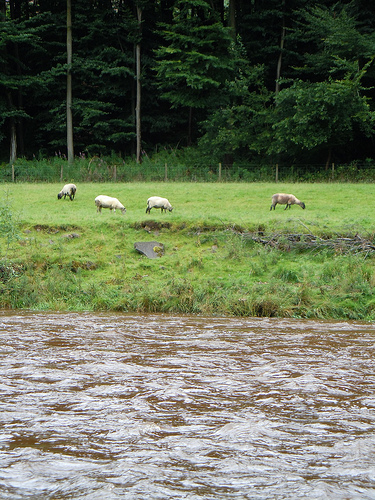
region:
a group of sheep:
[52, 172, 170, 225]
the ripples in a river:
[64, 435, 124, 482]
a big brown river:
[33, 313, 324, 486]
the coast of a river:
[153, 300, 191, 333]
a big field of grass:
[117, 267, 169, 304]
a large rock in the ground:
[126, 241, 174, 263]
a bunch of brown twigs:
[257, 221, 333, 255]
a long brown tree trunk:
[123, 87, 149, 154]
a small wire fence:
[123, 160, 261, 185]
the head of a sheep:
[117, 195, 129, 219]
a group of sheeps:
[37, 156, 365, 244]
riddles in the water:
[125, 433, 213, 485]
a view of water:
[1, 294, 372, 479]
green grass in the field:
[49, 229, 297, 305]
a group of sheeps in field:
[47, 173, 365, 248]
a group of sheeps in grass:
[54, 160, 345, 254]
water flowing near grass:
[34, 310, 349, 495]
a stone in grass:
[102, 224, 208, 279]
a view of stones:
[33, 210, 370, 271]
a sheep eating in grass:
[249, 173, 340, 238]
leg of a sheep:
[288, 201, 299, 211]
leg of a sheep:
[283, 200, 289, 215]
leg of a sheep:
[269, 203, 282, 211]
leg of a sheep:
[264, 200, 275, 216]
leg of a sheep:
[163, 203, 171, 211]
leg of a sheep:
[156, 205, 167, 214]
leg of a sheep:
[144, 204, 153, 213]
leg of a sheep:
[109, 204, 120, 213]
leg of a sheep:
[97, 205, 109, 214]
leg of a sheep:
[68, 191, 79, 201]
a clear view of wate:
[30, 296, 374, 491]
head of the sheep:
[51, 186, 66, 211]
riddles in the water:
[58, 379, 151, 449]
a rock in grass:
[117, 228, 203, 280]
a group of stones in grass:
[122, 214, 373, 259]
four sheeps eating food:
[44, 159, 374, 242]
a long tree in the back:
[43, 21, 96, 192]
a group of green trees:
[20, 13, 371, 162]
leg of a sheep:
[285, 199, 299, 216]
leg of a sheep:
[146, 209, 158, 213]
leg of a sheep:
[144, 203, 150, 211]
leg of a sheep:
[104, 202, 123, 219]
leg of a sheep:
[93, 202, 112, 221]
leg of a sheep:
[73, 191, 78, 198]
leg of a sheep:
[67, 189, 75, 202]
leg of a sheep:
[60, 188, 66, 200]